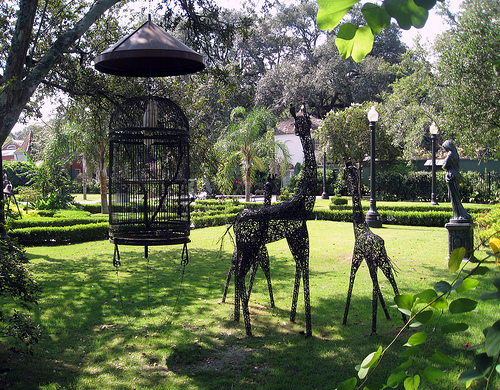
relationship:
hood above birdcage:
[93, 23, 209, 73] [99, 96, 201, 244]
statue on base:
[441, 140, 471, 220] [442, 214, 477, 264]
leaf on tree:
[329, 14, 383, 70] [0, 1, 438, 271]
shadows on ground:
[132, 313, 375, 361] [0, 215, 493, 386]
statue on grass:
[441, 140, 471, 220] [226, 273, 465, 388]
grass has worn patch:
[111, 299, 238, 388] [105, 336, 173, 377]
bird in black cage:
[143, 100, 158, 146] [103, 91, 194, 247]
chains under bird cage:
[111, 243, 188, 349] [107, 95, 192, 244]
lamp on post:
[365, 97, 389, 141] [367, 117, 380, 213]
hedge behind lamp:
[348, 163, 481, 198] [343, 96, 407, 148]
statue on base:
[427, 140, 463, 227] [445, 218, 480, 263]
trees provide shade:
[254, 54, 357, 194] [26, 240, 438, 387]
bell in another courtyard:
[97, 92, 222, 288] [6, 68, 496, 383]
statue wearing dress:
[441, 140, 471, 220] [443, 149, 471, 219]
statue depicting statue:
[441, 140, 471, 220] [441, 140, 471, 220]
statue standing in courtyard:
[441, 140, 471, 220] [6, 68, 496, 383]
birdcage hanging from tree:
[92, 16, 207, 266] [1, 0, 122, 147]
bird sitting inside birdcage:
[139, 97, 159, 144] [104, 94, 193, 249]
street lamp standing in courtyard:
[428, 121, 438, 204] [6, 68, 496, 383]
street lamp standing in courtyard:
[365, 105, 382, 227] [6, 68, 496, 383]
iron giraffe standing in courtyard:
[215, 102, 320, 337] [6, 68, 496, 383]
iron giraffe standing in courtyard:
[342, 162, 412, 334] [6, 68, 496, 383]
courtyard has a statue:
[6, 68, 496, 383] [428, 129, 485, 276]